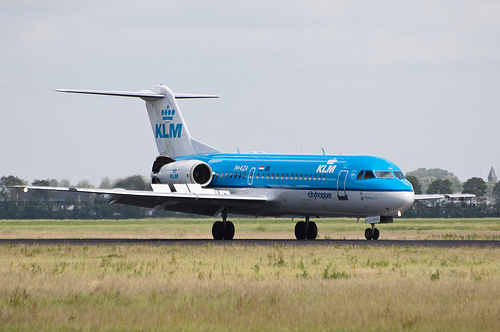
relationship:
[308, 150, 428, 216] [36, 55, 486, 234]
front of plane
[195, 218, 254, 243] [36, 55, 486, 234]
wheel of plane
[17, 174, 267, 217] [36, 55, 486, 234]
wing of plane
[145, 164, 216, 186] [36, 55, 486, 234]
engine of plane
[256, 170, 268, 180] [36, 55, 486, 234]
window of plane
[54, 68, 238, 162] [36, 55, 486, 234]
tail of plane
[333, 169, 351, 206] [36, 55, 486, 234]
door on plane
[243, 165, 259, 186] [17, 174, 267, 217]
door over wing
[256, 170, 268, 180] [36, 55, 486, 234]
window on plane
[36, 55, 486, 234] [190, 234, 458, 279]
plane on ground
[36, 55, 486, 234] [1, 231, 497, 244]
plane on runway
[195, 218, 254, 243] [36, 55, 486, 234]
wheel on plane